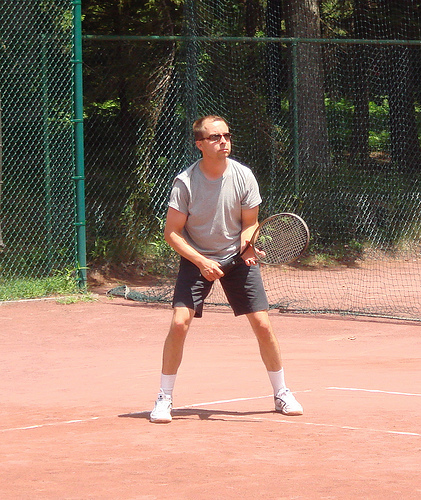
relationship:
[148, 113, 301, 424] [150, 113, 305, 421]
man has shorts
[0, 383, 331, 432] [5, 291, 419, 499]
chalk mark on field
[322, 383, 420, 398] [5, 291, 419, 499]
chalk mark on field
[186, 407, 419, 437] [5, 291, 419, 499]
chalk mark on field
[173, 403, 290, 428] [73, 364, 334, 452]
shadow on ground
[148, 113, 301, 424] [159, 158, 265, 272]
man wears shirt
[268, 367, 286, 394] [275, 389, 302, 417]
high-top sock on shoe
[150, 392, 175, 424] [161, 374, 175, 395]
shoe on high-top sock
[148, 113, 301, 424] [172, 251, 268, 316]
man has black shorts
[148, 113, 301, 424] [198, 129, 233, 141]
man has sunglasses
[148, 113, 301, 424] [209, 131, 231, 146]
man wears sunglasses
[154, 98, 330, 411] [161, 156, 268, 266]
man wears shirt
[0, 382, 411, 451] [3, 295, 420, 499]
lines on tennis court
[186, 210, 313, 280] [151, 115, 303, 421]
tennis and person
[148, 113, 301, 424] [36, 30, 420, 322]
man in fence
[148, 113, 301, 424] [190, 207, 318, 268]
man playing tennis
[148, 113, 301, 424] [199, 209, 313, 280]
man playing tennis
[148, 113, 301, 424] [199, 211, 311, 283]
man playing racket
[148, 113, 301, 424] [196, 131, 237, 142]
man in sunglasses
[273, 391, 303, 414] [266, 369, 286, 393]
shoe in high-top sock